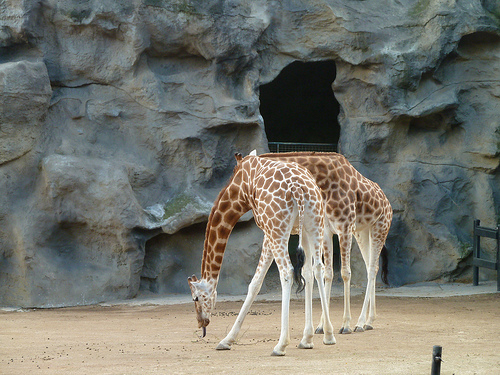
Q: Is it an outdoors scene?
A: Yes, it is outdoors.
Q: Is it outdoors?
A: Yes, it is outdoors.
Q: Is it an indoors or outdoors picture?
A: It is outdoors.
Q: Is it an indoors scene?
A: No, it is outdoors.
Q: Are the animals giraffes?
A: Yes, all the animals are giraffes.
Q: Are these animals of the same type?
A: Yes, all the animals are giraffes.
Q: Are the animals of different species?
A: No, all the animals are giraffes.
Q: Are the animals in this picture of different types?
A: No, all the animals are giraffes.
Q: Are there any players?
A: No, there are no players.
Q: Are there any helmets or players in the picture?
A: No, there are no players or helmets.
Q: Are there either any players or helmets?
A: No, there are no players or helmets.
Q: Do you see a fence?
A: Yes, there is a fence.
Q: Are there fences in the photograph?
A: Yes, there is a fence.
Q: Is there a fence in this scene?
A: Yes, there is a fence.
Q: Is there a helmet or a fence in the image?
A: Yes, there is a fence.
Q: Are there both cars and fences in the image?
A: No, there is a fence but no cars.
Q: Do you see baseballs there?
A: No, there are no baseballs.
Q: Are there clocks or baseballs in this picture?
A: No, there are no baseballs or clocks.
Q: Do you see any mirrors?
A: No, there are no mirrors.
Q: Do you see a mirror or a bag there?
A: No, there are no mirrors or bags.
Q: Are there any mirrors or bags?
A: No, there are no mirrors or bags.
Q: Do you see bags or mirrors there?
A: No, there are no mirrors or bags.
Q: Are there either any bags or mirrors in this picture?
A: No, there are no mirrors or bags.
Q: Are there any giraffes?
A: Yes, there is a giraffe.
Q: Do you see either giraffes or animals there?
A: Yes, there is a giraffe.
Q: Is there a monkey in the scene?
A: No, there are no monkeys.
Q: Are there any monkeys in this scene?
A: No, there are no monkeys.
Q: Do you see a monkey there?
A: No, there are no monkeys.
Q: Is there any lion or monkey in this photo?
A: No, there are no monkeys or lions.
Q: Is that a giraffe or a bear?
A: That is a giraffe.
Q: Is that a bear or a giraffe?
A: That is a giraffe.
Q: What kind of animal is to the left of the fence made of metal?
A: The animal is a giraffe.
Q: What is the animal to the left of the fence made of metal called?
A: The animal is a giraffe.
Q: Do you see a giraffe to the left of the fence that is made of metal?
A: Yes, there is a giraffe to the left of the fence.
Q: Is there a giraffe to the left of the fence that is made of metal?
A: Yes, there is a giraffe to the left of the fence.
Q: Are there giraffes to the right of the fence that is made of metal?
A: No, the giraffe is to the left of the fence.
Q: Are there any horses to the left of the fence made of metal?
A: No, there is a giraffe to the left of the fence.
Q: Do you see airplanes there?
A: No, there are no airplanes.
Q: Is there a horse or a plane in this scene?
A: No, there are no airplanes or horses.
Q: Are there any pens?
A: No, there are no pens.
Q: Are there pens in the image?
A: No, there are no pens.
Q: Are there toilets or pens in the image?
A: No, there are no pens or toilets.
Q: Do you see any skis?
A: No, there are no skis.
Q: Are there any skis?
A: No, there are no skis.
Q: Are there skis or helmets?
A: No, there are no skis or helmets.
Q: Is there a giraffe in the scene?
A: Yes, there is a giraffe.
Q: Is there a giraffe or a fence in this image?
A: Yes, there is a giraffe.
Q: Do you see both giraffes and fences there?
A: Yes, there are both a giraffe and a fence.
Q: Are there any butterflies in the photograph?
A: No, there are no butterflies.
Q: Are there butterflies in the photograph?
A: No, there are no butterflies.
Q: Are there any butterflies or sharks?
A: No, there are no butterflies or sharks.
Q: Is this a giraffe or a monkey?
A: This is a giraffe.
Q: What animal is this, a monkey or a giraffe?
A: This is a giraffe.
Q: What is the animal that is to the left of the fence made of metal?
A: The animal is a giraffe.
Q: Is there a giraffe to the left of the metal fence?
A: Yes, there is a giraffe to the left of the fence.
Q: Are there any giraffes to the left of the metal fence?
A: Yes, there is a giraffe to the left of the fence.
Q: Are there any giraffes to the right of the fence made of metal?
A: No, the giraffe is to the left of the fence.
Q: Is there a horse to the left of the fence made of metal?
A: No, there is a giraffe to the left of the fence.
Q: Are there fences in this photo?
A: Yes, there is a fence.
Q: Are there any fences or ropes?
A: Yes, there is a fence.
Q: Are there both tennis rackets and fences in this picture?
A: No, there is a fence but no rackets.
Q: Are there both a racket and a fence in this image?
A: No, there is a fence but no rackets.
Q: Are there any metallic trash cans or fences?
A: Yes, there is a metal fence.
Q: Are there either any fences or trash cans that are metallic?
A: Yes, the fence is metallic.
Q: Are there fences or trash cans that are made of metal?
A: Yes, the fence is made of metal.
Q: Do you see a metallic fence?
A: Yes, there is a metal fence.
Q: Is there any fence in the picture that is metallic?
A: Yes, there is a fence that is metallic.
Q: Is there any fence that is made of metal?
A: Yes, there is a fence that is made of metal.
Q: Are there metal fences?
A: Yes, there is a fence that is made of metal.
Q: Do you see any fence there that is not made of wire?
A: Yes, there is a fence that is made of metal.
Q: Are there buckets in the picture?
A: No, there are no buckets.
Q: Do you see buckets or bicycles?
A: No, there are no buckets or bicycles.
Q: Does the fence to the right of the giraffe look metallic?
A: Yes, the fence is metallic.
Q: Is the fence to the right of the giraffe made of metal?
A: Yes, the fence is made of metal.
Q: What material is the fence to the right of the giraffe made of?
A: The fence is made of metal.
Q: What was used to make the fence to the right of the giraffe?
A: The fence is made of metal.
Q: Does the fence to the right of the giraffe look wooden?
A: No, the fence is metallic.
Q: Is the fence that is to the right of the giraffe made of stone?
A: No, the fence is made of metal.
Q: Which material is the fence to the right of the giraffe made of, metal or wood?
A: The fence is made of metal.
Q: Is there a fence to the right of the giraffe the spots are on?
A: Yes, there is a fence to the right of the giraffe.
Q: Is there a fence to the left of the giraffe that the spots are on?
A: No, the fence is to the right of the giraffe.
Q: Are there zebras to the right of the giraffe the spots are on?
A: No, there is a fence to the right of the giraffe.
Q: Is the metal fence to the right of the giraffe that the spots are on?
A: Yes, the fence is to the right of the giraffe.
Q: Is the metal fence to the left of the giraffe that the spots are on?
A: No, the fence is to the right of the giraffe.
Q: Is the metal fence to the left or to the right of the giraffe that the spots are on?
A: The fence is to the right of the giraffe.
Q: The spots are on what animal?
A: The spots are on the giraffe.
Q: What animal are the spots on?
A: The spots are on the giraffe.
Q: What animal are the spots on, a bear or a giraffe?
A: The spots are on a giraffe.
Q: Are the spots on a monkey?
A: No, the spots are on a giraffe.